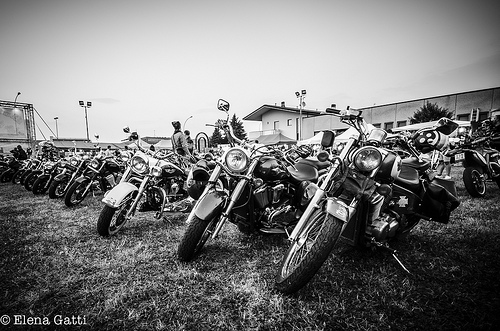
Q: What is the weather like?
A: It is cloudy.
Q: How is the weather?
A: It is cloudy.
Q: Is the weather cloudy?
A: Yes, it is cloudy.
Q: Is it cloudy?
A: Yes, it is cloudy.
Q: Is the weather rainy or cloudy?
A: It is cloudy.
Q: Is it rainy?
A: No, it is cloudy.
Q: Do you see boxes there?
A: No, there are no boxes.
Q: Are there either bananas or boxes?
A: No, there are no boxes or bananas.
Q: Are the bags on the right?
A: Yes, the bags are on the right of the image.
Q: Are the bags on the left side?
A: No, the bags are on the right of the image.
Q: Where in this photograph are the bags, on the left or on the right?
A: The bags are on the right of the image.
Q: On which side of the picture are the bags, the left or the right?
A: The bags are on the right of the image.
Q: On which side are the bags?
A: The bags are on the right of the image.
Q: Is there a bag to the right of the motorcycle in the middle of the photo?
A: Yes, there are bags to the right of the motorcycle.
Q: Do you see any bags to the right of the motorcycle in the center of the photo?
A: Yes, there are bags to the right of the motorcycle.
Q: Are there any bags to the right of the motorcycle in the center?
A: Yes, there are bags to the right of the motorcycle.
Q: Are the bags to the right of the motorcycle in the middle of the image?
A: Yes, the bags are to the right of the motorcycle.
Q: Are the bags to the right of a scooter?
A: No, the bags are to the right of the motorcycle.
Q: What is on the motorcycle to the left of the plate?
A: The bags are on the motorbike.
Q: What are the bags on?
A: The bags are on the motorcycle.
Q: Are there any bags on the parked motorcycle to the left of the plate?
A: Yes, there are bags on the motorbike.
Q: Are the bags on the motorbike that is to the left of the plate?
A: Yes, the bags are on the motorbike.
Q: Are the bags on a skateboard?
A: No, the bags are on the motorbike.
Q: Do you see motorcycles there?
A: Yes, there is a motorcycle.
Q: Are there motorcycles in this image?
A: Yes, there is a motorcycle.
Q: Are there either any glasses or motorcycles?
A: Yes, there is a motorcycle.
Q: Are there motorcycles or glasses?
A: Yes, there is a motorcycle.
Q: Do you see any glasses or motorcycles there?
A: Yes, there is a motorcycle.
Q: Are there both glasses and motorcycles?
A: No, there is a motorcycle but no glasses.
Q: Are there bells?
A: No, there are no bells.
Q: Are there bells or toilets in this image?
A: No, there are no bells or toilets.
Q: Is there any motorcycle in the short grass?
A: Yes, there is a motorcycle in the grass.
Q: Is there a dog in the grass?
A: No, there is a motorcycle in the grass.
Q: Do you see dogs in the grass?
A: No, there is a motorcycle in the grass.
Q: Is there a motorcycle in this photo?
A: Yes, there is a motorcycle.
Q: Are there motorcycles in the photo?
A: Yes, there is a motorcycle.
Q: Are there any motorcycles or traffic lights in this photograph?
A: Yes, there is a motorcycle.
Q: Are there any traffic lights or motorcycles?
A: Yes, there is a motorcycle.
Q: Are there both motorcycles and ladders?
A: No, there is a motorcycle but no ladders.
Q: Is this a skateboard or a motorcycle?
A: This is a motorcycle.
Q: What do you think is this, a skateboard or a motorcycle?
A: This is a motorcycle.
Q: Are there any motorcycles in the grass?
A: Yes, there is a motorcycle in the grass.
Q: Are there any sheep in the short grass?
A: No, there is a motorcycle in the grass.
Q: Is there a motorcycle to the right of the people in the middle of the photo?
A: Yes, there is a motorcycle to the right of the people.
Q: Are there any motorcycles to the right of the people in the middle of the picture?
A: Yes, there is a motorcycle to the right of the people.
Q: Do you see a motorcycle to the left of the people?
A: No, the motorcycle is to the right of the people.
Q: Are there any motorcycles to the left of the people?
A: No, the motorcycle is to the right of the people.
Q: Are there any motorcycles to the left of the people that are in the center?
A: No, the motorcycle is to the right of the people.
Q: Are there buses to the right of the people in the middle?
A: No, there is a motorcycle to the right of the people.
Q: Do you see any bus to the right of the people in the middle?
A: No, there is a motorcycle to the right of the people.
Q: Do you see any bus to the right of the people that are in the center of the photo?
A: No, there is a motorcycle to the right of the people.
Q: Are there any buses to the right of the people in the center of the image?
A: No, there is a motorcycle to the right of the people.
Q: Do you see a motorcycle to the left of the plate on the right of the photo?
A: Yes, there is a motorcycle to the left of the plate.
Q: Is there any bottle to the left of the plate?
A: No, there is a motorcycle to the left of the plate.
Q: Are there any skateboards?
A: No, there are no skateboards.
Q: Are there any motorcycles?
A: Yes, there is a motorcycle.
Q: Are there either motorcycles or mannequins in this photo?
A: Yes, there is a motorcycle.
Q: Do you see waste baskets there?
A: No, there are no waste baskets.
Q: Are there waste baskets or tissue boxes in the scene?
A: No, there are no waste baskets or tissue boxes.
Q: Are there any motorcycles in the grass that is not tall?
A: Yes, there is a motorcycle in the grass.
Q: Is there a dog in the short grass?
A: No, there is a motorcycle in the grass.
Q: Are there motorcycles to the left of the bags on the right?
A: Yes, there is a motorcycle to the left of the bags.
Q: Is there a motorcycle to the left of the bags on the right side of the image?
A: Yes, there is a motorcycle to the left of the bags.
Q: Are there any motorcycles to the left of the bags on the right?
A: Yes, there is a motorcycle to the left of the bags.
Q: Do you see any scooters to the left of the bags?
A: No, there is a motorcycle to the left of the bags.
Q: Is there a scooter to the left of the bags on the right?
A: No, there is a motorcycle to the left of the bags.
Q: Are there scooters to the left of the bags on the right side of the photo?
A: No, there is a motorcycle to the left of the bags.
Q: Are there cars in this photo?
A: No, there are no cars.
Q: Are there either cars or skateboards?
A: No, there are no cars or skateboards.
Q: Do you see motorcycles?
A: Yes, there is a motorcycle.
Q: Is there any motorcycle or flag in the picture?
A: Yes, there is a motorcycle.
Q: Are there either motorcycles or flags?
A: Yes, there is a motorcycle.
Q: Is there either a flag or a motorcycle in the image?
A: Yes, there is a motorcycle.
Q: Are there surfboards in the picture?
A: No, there are no surfboards.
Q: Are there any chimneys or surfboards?
A: No, there are no surfboards or chimneys.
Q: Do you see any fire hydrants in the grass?
A: No, there is a motorcycle in the grass.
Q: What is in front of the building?
A: The motorcycle is in front of the building.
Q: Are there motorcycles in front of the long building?
A: Yes, there is a motorcycle in front of the building.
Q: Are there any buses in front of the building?
A: No, there is a motorcycle in front of the building.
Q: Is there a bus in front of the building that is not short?
A: No, there is a motorcycle in front of the building.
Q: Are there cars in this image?
A: No, there are no cars.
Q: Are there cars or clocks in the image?
A: No, there are no cars or clocks.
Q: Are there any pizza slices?
A: No, there are no pizza slices.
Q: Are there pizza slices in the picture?
A: No, there are no pizza slices.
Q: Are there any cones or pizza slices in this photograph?
A: No, there are no pizza slices or cones.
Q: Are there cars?
A: No, there are no cars.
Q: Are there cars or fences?
A: No, there are no cars or fences.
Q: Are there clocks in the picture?
A: No, there are no clocks.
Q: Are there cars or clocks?
A: No, there are no clocks or cars.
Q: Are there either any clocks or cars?
A: No, there are no clocks or cars.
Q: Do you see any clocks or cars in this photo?
A: No, there are no clocks or cars.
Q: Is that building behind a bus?
A: No, the building is behind the motorcycle.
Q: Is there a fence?
A: No, there are no fences.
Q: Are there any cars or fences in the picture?
A: No, there are no fences or cars.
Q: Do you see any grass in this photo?
A: Yes, there is grass.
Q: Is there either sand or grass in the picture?
A: Yes, there is grass.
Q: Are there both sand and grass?
A: No, there is grass but no sand.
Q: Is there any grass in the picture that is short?
A: Yes, there is short grass.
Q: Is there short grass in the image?
A: Yes, there is short grass.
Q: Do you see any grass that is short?
A: Yes, there is grass that is short.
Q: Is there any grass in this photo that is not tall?
A: Yes, there is short grass.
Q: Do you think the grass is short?
A: Yes, the grass is short.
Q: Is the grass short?
A: Yes, the grass is short.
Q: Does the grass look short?
A: Yes, the grass is short.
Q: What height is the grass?
A: The grass is short.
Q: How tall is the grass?
A: The grass is short.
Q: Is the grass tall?
A: No, the grass is short.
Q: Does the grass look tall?
A: No, the grass is short.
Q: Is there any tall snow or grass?
A: No, there is grass but it is short.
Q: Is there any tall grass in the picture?
A: No, there is grass but it is short.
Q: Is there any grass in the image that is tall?
A: No, there is grass but it is short.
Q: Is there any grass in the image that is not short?
A: No, there is grass but it is short.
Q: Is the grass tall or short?
A: The grass is short.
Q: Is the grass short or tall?
A: The grass is short.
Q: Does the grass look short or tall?
A: The grass is short.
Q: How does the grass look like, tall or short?
A: The grass is short.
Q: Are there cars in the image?
A: No, there are no cars.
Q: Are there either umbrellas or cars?
A: No, there are no cars or umbrellas.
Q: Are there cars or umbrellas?
A: No, there are no cars or umbrellas.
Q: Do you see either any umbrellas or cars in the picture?
A: No, there are no cars or umbrellas.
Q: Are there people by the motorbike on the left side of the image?
A: Yes, there are people by the motorcycle.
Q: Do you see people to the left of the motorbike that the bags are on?
A: Yes, there are people to the left of the motorcycle.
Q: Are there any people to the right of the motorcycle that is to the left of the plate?
A: No, the people are to the left of the motorbike.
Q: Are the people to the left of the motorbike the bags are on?
A: Yes, the people are to the left of the motorcycle.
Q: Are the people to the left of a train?
A: No, the people are to the left of the motorcycle.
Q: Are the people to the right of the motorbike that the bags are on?
A: No, the people are to the left of the motorbike.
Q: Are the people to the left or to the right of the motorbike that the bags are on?
A: The people are to the left of the motorbike.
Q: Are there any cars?
A: No, there are no cars.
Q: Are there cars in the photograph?
A: No, there are no cars.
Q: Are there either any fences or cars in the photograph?
A: No, there are no cars or fences.